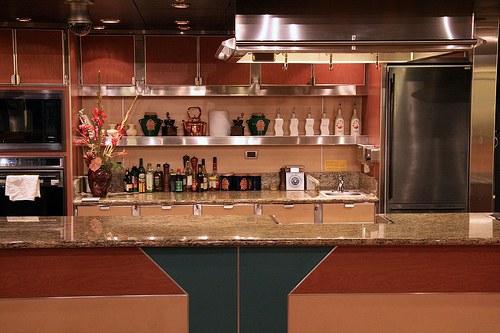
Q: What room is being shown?
A: Kitchen.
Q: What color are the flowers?
A: Pink.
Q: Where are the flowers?
A: A vase.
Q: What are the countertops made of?
A: Marble.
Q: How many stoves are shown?
A: Two.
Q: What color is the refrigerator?
A: Silver.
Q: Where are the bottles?
A: The shelves.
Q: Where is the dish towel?
A: On the stove.